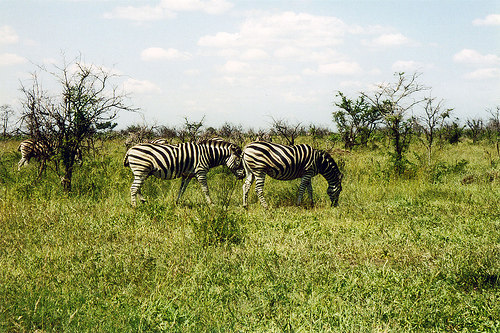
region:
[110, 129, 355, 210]
two zebras walking through grass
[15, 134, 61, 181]
zebra behind the tree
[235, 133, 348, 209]
zebra eating the grass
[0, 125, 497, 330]
grass that zebras are walking in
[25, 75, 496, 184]
trees along the horizon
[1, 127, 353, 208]
three zebras walking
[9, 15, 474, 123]
white clouds in the blue sky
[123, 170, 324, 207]
legs of two zebras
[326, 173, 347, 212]
head of zebra eating grass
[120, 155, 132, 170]
tail of zebra standing up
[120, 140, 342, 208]
Two zebras in the grass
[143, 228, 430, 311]
Grass beneath the zebras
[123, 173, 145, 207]
The back leg of the zebra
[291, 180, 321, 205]
The front leg of the zebra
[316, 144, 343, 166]
The mane of the zebra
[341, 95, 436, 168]
Trees near the zebras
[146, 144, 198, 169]
The zebra has black and white stripes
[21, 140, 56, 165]
A zebra behind a tree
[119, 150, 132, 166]
The tail of the zebra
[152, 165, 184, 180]
Stomach of the zebra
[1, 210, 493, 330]
brown and green grass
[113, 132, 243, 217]
a black and white zebra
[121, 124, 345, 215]
two zebras standing together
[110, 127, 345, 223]
one zebra infront of the other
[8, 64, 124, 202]
a small bare tree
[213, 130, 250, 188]
a zebra's head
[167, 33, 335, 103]
white clouds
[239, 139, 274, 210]
two hine legs of a zebra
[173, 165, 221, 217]
two front legs of a zebra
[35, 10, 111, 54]
a piece of blue sky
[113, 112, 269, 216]
a zebra in a field of grass.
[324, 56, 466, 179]
a tree with green leaves.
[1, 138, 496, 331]
a field of green grass.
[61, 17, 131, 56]
a section of clear blue sky.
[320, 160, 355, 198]
the head of a giraffe.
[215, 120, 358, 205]
a giraffe eating grass.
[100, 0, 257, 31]
a gray cloud in a sky.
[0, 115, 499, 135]
wild brush growing in a field.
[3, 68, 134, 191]
a tree with leaves.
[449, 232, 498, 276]
a shadow on grass.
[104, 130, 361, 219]
two zebras in a field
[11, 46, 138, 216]
an animal behind a tree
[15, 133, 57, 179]
the animal is brown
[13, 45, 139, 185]
the tree has no leaves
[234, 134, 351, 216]
the zebra is eating grass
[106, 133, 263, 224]
the zebra is behind the other zebra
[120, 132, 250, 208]
the zebra is striped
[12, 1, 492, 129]
a few scattered clouds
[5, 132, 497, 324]
the grass is rough and bushy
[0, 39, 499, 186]
the trees are spiky